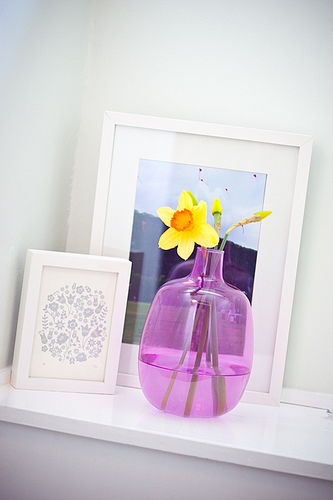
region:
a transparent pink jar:
[137, 246, 249, 417]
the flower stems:
[164, 296, 226, 415]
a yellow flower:
[151, 192, 213, 255]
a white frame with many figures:
[18, 251, 131, 394]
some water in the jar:
[133, 354, 251, 419]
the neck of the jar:
[190, 247, 225, 282]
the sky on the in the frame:
[116, 125, 287, 255]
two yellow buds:
[211, 197, 272, 255]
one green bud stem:
[221, 232, 227, 250]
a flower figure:
[81, 322, 89, 344]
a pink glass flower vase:
[137, 247, 254, 417]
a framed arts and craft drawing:
[11, 247, 131, 394]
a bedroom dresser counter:
[0, 411, 332, 499]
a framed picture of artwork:
[96, 109, 311, 189]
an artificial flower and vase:
[157, 189, 218, 257]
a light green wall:
[0, 0, 332, 108]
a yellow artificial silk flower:
[155, 190, 218, 258]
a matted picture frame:
[115, 124, 299, 188]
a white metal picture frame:
[102, 105, 131, 131]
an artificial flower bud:
[220, 208, 274, 247]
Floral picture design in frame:
[45, 283, 102, 370]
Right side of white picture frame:
[117, 275, 124, 346]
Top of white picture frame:
[30, 255, 152, 272]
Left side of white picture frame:
[14, 255, 30, 389]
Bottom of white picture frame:
[20, 375, 116, 399]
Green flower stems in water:
[170, 306, 228, 415]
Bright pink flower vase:
[142, 250, 255, 416]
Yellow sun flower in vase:
[161, 202, 218, 246]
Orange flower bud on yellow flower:
[170, 209, 198, 236]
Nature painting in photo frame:
[132, 151, 279, 286]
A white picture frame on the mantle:
[13, 250, 130, 387]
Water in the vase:
[139, 353, 248, 415]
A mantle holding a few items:
[2, 371, 331, 499]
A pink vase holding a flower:
[138, 249, 255, 417]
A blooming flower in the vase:
[156, 189, 265, 414]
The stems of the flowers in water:
[161, 291, 224, 416]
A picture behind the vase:
[88, 111, 315, 407]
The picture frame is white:
[89, 111, 314, 404]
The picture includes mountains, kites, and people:
[122, 157, 266, 358]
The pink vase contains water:
[140, 248, 254, 417]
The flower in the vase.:
[153, 197, 223, 256]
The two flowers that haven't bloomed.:
[211, 195, 267, 239]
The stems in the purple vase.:
[156, 280, 223, 414]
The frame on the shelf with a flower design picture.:
[16, 240, 128, 404]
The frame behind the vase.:
[100, 120, 300, 363]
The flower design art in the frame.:
[45, 279, 103, 369]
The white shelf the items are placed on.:
[7, 374, 331, 478]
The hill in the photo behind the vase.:
[136, 212, 254, 313]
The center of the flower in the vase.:
[167, 208, 191, 235]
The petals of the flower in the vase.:
[159, 193, 220, 259]